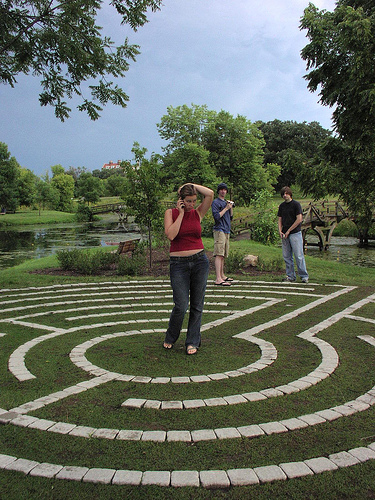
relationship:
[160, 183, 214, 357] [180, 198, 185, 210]
girl with cellphone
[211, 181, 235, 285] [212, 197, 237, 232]
guy in shirt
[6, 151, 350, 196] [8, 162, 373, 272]
pond surrounds te park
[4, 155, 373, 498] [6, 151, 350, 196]
another part of pond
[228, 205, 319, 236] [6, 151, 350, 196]
briddge across pond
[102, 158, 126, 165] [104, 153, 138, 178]
roof of house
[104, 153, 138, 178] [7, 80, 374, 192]
house in background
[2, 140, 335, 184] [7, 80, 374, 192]
trees in background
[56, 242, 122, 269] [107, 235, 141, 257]
shrubs next to bench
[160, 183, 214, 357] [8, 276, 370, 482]
girl standing in maze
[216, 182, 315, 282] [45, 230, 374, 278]
men standing on edge of maze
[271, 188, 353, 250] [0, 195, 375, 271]
structure over pond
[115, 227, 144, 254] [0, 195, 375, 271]
bench facing pond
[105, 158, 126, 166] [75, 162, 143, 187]
building peeking over treetops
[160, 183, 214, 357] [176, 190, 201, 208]
girl holding head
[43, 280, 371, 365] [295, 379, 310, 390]
maze made with squarestones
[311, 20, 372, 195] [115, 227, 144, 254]
tree behind bench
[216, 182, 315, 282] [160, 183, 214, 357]
men looking at girl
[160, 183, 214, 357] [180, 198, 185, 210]
girl using cellphone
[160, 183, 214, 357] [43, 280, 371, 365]
girl in maze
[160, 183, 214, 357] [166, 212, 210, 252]
girl wears top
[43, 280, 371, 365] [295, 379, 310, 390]
maze made of squarestones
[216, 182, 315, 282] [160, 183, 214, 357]
boys looking at girl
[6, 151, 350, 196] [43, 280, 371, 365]
pond behind maze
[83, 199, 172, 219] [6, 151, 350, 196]
briddge crosses over pond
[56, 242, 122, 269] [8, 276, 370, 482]
grass grows under stonemaze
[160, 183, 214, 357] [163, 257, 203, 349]
girl wearing jeans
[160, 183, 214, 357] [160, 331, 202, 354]
girl wering sandals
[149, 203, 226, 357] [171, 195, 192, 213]
girl on cellphone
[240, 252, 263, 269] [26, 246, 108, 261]
flat rocks on grass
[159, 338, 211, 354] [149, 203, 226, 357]
summer sandals on feet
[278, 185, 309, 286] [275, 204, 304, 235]
guy in blackshirt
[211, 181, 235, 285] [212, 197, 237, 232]
guy in blueshirt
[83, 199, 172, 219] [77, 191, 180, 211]
briddge over water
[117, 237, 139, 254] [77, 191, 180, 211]
bench by water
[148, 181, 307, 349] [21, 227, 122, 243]
people by water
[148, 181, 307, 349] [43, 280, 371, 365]
people standing on maze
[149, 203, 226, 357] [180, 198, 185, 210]
girl taking on cellphone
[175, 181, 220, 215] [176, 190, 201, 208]
arm over her head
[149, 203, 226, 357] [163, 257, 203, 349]
girl wearing jeans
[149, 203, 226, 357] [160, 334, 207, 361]
girl wearing flipflops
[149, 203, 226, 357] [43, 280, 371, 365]
girl solved maze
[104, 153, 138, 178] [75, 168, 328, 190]
house on hill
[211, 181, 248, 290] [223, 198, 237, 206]
guy with camera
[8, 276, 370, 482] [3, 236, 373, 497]
sundial on ground